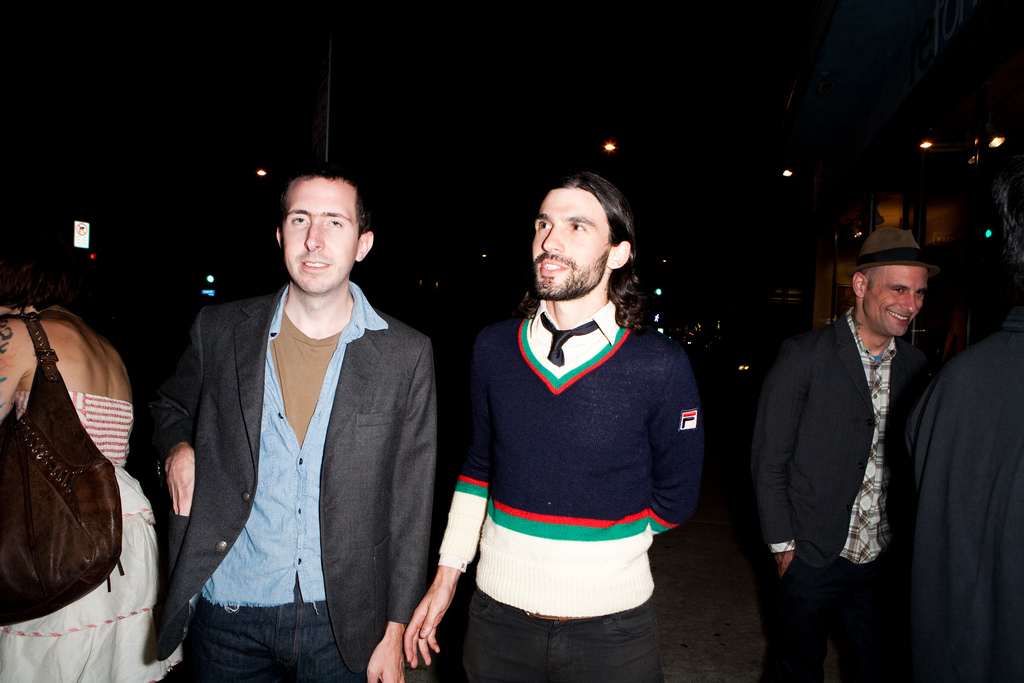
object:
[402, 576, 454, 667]
hand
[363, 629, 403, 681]
hand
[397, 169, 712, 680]
man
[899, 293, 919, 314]
nose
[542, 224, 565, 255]
nose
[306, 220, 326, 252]
nose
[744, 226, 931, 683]
man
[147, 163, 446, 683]
man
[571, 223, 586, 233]
eye